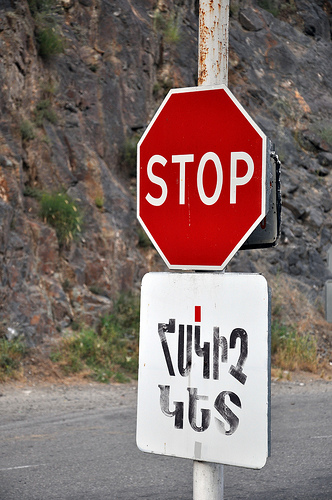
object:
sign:
[135, 272, 271, 468]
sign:
[239, 136, 281, 250]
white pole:
[191, 460, 223, 499]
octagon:
[134, 84, 266, 271]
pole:
[191, 0, 230, 499]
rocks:
[0, 0, 331, 376]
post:
[191, 461, 224, 499]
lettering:
[157, 318, 248, 385]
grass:
[0, 290, 138, 384]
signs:
[136, 83, 270, 469]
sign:
[136, 84, 267, 271]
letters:
[145, 151, 254, 208]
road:
[0, 383, 331, 498]